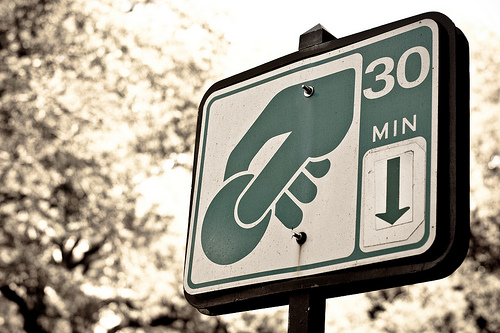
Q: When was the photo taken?
A: Daytime.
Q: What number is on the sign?
A: 30.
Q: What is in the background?
A: Trees.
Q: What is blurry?
A: Background.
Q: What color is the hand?
A: Green.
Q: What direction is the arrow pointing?
A: Down.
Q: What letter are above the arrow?
A: MIN.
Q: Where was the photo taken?
A: Near the 30 min parking.